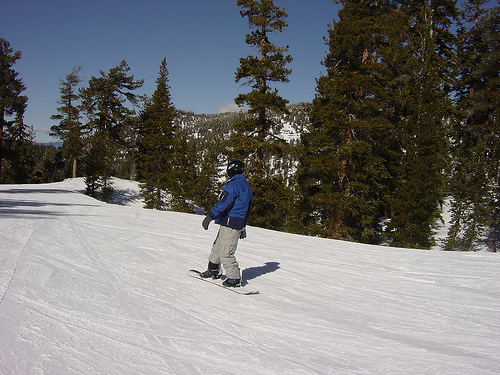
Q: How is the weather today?
A: It is clear.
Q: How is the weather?
A: It is clear.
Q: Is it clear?
A: Yes, it is clear.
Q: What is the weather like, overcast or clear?
A: It is clear.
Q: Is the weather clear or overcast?
A: It is clear.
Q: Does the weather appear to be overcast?
A: No, it is clear.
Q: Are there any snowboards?
A: Yes, there is a snowboard.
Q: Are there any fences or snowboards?
A: Yes, there is a snowboard.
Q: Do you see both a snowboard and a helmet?
A: Yes, there are both a snowboard and a helmet.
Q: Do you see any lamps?
A: No, there are no lamps.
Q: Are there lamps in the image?
A: No, there are no lamps.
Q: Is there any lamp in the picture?
A: No, there are no lamps.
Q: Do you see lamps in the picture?
A: No, there are no lamps.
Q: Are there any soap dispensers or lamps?
A: No, there are no lamps or soap dispensers.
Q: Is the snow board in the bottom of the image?
A: Yes, the snow board is in the bottom of the image.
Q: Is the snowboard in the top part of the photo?
A: No, the snowboard is in the bottom of the image.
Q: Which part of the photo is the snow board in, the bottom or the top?
A: The snow board is in the bottom of the image.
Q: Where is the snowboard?
A: The snowboard is on the snow.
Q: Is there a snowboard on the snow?
A: Yes, there is a snowboard on the snow.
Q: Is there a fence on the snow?
A: No, there is a snowboard on the snow.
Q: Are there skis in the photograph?
A: No, there are no skis.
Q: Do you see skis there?
A: No, there are no skis.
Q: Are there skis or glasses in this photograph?
A: No, there are no skis or glasses.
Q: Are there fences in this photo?
A: No, there are no fences.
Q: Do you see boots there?
A: Yes, there are boots.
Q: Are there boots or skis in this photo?
A: Yes, there are boots.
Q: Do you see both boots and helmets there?
A: Yes, there are both boots and a helmet.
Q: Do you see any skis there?
A: No, there are no skis.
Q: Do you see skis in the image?
A: No, there are no skis.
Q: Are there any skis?
A: No, there are no skis.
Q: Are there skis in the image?
A: No, there are no skis.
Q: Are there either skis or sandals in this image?
A: No, there are no skis or sandals.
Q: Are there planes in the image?
A: No, there are no planes.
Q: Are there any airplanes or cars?
A: No, there are no airplanes or cars.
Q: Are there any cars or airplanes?
A: No, there are no airplanes or cars.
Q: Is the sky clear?
A: Yes, the sky is clear.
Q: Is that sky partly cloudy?
A: No, the sky is clear.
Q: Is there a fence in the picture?
A: No, there are no fences.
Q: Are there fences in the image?
A: No, there are no fences.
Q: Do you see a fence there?
A: No, there are no fences.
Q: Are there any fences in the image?
A: No, there are no fences.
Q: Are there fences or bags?
A: No, there are no fences or bags.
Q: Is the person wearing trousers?
A: Yes, the person is wearing trousers.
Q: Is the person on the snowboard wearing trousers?
A: Yes, the person is wearing trousers.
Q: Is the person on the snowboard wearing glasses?
A: No, the person is wearing trousers.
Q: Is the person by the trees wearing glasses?
A: No, the person is wearing trousers.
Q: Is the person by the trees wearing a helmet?
A: Yes, the person is wearing a helmet.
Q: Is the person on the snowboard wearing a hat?
A: No, the person is wearing a helmet.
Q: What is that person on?
A: The person is on the snow board.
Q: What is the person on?
A: The person is on the snow board.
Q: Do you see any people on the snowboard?
A: Yes, there is a person on the snowboard.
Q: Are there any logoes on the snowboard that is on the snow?
A: No, there is a person on the snowboard.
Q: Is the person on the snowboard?
A: Yes, the person is on the snowboard.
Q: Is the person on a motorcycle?
A: No, the person is on the snowboard.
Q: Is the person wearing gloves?
A: Yes, the person is wearing gloves.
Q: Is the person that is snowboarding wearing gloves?
A: Yes, the person is wearing gloves.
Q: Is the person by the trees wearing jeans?
A: No, the person is wearing gloves.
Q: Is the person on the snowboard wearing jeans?
A: No, the person is wearing gloves.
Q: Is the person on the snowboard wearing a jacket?
A: Yes, the person is wearing a jacket.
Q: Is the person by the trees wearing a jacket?
A: Yes, the person is wearing a jacket.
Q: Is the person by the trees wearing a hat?
A: No, the person is wearing a jacket.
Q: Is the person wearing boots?
A: Yes, the person is wearing boots.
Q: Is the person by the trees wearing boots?
A: Yes, the person is wearing boots.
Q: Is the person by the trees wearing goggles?
A: No, the person is wearing boots.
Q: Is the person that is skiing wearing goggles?
A: No, the person is wearing boots.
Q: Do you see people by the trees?
A: Yes, there is a person by the trees.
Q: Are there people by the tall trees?
A: Yes, there is a person by the trees.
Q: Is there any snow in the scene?
A: Yes, there is snow.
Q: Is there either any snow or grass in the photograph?
A: Yes, there is snow.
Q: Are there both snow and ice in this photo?
A: No, there is snow but no ice.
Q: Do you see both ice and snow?
A: No, there is snow but no ice.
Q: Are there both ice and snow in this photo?
A: No, there is snow but no ice.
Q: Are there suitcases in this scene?
A: No, there are no suitcases.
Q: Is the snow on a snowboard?
A: Yes, the snow is on a snowboard.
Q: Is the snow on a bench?
A: No, the snow is on a snowboard.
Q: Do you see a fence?
A: No, there are no fences.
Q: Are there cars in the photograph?
A: No, there are no cars.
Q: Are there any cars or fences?
A: No, there are no cars or fences.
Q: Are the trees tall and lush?
A: Yes, the trees are tall and lush.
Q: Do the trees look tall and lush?
A: Yes, the trees are tall and lush.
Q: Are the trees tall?
A: Yes, the trees are tall.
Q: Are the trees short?
A: No, the trees are tall.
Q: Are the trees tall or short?
A: The trees are tall.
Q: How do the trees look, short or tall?
A: The trees are tall.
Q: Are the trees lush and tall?
A: Yes, the trees are lush and tall.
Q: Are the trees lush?
A: Yes, the trees are lush.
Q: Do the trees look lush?
A: Yes, the trees are lush.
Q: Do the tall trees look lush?
A: Yes, the trees are lush.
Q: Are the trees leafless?
A: No, the trees are lush.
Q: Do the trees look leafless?
A: No, the trees are lush.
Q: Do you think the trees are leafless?
A: No, the trees are lush.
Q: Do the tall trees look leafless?
A: No, the trees are lush.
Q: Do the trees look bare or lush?
A: The trees are lush.